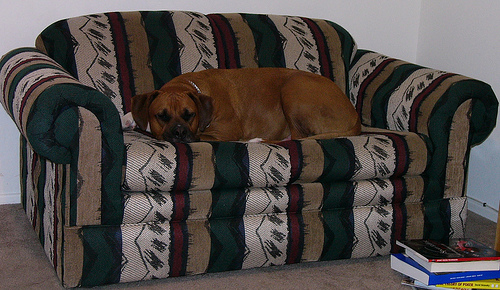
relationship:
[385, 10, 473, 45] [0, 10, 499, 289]
white wall behind couch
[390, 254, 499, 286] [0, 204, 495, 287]
blue book on ground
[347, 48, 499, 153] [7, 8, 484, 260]
arm rest on couch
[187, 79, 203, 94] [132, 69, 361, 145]
collar on dog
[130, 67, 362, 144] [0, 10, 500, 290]
bullmastiff resting on couch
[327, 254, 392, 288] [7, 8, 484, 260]
carpet beneath couch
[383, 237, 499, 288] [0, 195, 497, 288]
books on floor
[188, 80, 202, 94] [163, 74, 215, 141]
collar on neck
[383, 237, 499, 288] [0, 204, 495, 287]
books on ground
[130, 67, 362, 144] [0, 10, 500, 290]
bullmastiff on love seat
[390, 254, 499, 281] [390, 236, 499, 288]
blue book in stack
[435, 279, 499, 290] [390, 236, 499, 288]
book in stack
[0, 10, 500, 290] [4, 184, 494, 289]
love seat on carpet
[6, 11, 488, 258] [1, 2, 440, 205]
love seat in front of white wall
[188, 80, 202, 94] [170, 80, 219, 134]
collar around neck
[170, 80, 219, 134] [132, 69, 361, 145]
neck of a dog